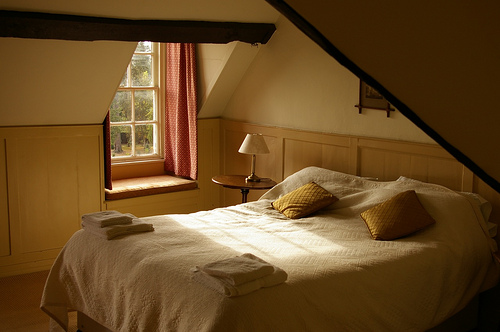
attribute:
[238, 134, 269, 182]
table lamp — tiny, light, small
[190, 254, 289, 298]
folded towels — stacked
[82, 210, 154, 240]
folded towels — stacked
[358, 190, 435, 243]
pillow — small, beige, gold, yellow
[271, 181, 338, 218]
pillow — gold, yellow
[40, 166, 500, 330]
bedspread — white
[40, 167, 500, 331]
bed — white, king sized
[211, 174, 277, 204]
side table — round, wooden, small, oval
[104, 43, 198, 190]
curtains — hanging, red, white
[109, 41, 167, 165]
window — white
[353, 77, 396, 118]
picture — framed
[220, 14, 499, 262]
wall — angled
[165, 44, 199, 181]
curtain panel — red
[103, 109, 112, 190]
curtain panel — red